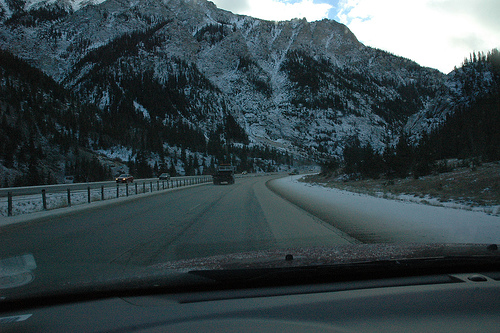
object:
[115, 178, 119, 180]
headlight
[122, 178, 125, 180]
headlight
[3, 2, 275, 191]
mountain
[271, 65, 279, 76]
snow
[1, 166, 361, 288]
road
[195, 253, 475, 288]
hood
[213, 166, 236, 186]
car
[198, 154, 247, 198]
truck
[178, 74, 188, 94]
tree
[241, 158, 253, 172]
tree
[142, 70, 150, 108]
tree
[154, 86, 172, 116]
tree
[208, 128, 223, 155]
tree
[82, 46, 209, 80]
hill top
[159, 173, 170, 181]
car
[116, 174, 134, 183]
car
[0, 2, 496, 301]
car windshield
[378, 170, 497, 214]
snow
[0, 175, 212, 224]
fence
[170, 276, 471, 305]
vent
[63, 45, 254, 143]
mountains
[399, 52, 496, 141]
mountainside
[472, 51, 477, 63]
tree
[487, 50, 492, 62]
tree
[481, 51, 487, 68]
tree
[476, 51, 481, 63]
tree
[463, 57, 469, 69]
tree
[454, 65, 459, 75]
tree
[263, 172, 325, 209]
curve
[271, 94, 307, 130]
snow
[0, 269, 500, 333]
dashboard